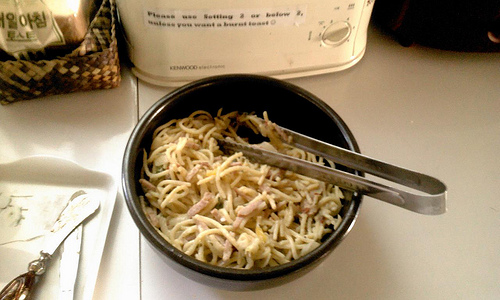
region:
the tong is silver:
[209, 113, 426, 253]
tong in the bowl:
[222, 115, 444, 244]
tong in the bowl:
[156, 75, 438, 294]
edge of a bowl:
[246, 260, 271, 280]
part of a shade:
[377, 258, 407, 281]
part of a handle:
[368, 158, 407, 249]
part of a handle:
[383, 163, 422, 230]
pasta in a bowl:
[143, 100, 405, 295]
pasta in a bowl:
[144, 88, 297, 265]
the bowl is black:
[111, 83, 342, 299]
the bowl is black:
[176, 67, 348, 152]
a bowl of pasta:
[98, 73, 394, 284]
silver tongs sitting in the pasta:
[227, 114, 462, 234]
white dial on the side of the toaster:
[317, 15, 352, 51]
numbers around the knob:
[312, 15, 352, 50]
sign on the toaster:
[141, 6, 308, 33]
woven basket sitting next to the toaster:
[2, 1, 132, 106]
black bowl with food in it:
[116, 64, 376, 286]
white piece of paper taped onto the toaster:
[141, 2, 318, 32]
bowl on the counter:
[101, 75, 383, 296]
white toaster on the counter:
[119, 3, 379, 104]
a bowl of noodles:
[121, 57, 388, 276]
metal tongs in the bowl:
[208, 98, 451, 253]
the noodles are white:
[124, 120, 301, 246]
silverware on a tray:
[6, 165, 99, 287]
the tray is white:
[5, 152, 125, 291]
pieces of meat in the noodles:
[161, 177, 273, 254]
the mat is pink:
[177, 182, 271, 232]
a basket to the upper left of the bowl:
[0, 9, 125, 103]